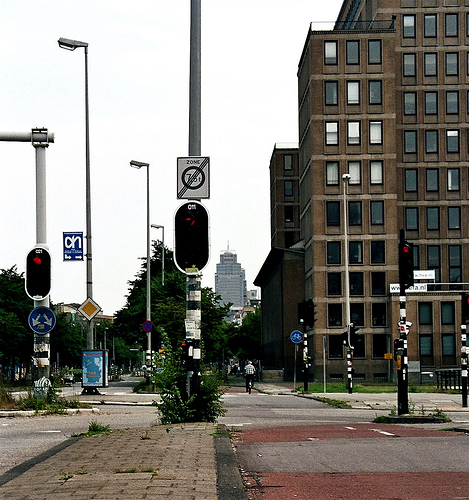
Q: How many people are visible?
A: One.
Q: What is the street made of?
A: Brick.